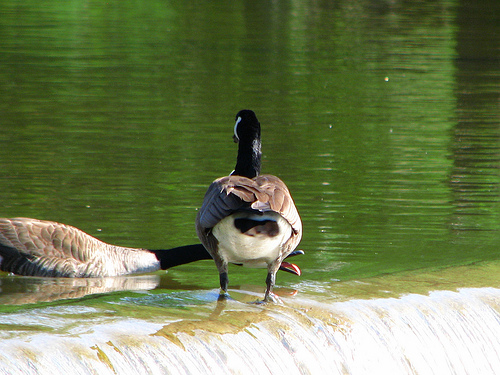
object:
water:
[1, 1, 499, 372]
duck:
[194, 107, 306, 305]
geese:
[0, 214, 307, 307]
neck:
[234, 143, 263, 171]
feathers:
[196, 175, 271, 229]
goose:
[197, 233, 300, 311]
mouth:
[278, 242, 305, 278]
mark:
[233, 114, 243, 140]